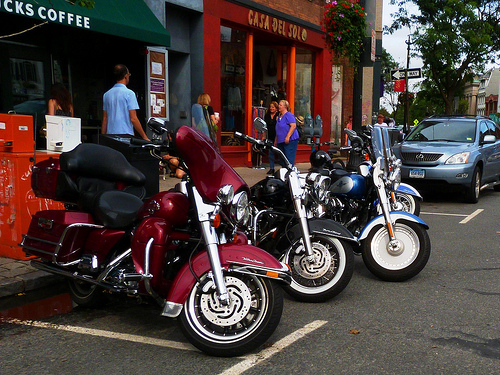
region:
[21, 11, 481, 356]
Motorcycles are parked on the lot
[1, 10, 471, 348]
Motorcycles are parked in front of the business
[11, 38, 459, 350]
The motorcycles are sitting side by side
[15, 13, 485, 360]
People are walking around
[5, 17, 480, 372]
The people are patronizing a business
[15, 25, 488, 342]
The people are in a city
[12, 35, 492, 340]
The people are out in the daytime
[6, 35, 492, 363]
The people are taking their lunch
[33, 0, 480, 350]
The people are on their lunch break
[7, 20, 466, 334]
The people are enjoying their day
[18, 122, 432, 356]
four motorcycles parked on the street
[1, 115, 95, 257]
two newspaper machines on the sidewalk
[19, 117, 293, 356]
a maroon motorcycle parked on the street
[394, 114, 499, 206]
a blue car parked on the street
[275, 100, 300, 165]
a woman wearing a blue shirt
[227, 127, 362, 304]
a black motorcycle parked on the street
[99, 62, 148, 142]
a balding man wearing blue shirt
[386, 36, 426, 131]
a one way street sign pointing left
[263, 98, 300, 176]
two women walking on the sidewalk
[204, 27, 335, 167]
a building that is painted red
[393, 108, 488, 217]
the car is parked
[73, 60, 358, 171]
people at the sidewalk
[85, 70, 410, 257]
people at the sidewalk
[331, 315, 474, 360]
The ground is made of asphalt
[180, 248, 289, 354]
The front wheel of the motorcycle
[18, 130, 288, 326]
The motorcycle is the color burgundy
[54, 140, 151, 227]
The seat of the motorcycle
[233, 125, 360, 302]
The color of the motorcycle is black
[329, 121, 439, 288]
The color of the motorcycle is blue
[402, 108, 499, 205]
The car is parked on the street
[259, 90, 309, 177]
Two women standing on the sidewalk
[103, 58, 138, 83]
The man has black hair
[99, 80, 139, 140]
The man has on a blue shirt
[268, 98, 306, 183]
The woman is wearing a purple shirt.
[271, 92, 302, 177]
The woman is wearing blue pants.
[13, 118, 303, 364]
The motorcycle is parked.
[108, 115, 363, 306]
The motorcycle is parked.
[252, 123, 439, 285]
The motorcycle is parked.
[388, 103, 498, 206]
The car is blue.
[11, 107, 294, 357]
The motorcycle is cranberry color.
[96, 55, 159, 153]
The man is wearing a shirt.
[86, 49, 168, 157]
The man's shirt is blue.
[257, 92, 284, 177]
The woman's blouse is black.